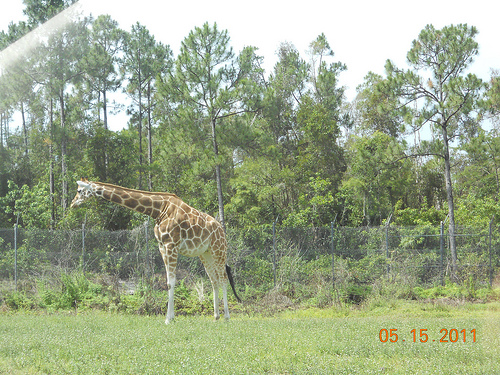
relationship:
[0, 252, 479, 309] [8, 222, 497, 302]
bush growing alongside fence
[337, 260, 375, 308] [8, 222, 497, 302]
bush growing alongside fence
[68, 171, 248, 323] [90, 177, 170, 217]
giraffe lowering neck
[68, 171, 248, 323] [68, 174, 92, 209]
giraffe bowing head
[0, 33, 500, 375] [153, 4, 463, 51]
area of sky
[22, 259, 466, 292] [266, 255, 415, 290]
row of shrubs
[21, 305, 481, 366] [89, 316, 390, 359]
field of grass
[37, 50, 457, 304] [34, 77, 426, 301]
exhibit at zoo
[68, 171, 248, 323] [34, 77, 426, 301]
giraffe at zoo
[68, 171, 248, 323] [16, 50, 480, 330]
giraffe at zoo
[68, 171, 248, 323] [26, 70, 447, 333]
giraffe in enclosure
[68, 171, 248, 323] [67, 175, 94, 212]
giraffe has head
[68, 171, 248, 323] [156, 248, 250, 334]
giraffe has legs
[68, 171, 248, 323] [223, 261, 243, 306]
giraffe has tail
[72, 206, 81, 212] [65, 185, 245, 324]
nose on giraffe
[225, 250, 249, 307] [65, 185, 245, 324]
tail on giraffe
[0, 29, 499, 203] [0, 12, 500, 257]
leaves in tree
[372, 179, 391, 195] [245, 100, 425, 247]
leaves in tree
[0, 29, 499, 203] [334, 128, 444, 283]
leaves in tree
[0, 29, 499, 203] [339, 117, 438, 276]
leaves in tree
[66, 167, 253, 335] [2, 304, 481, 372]
animal in field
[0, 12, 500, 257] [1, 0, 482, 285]
tree standing in woods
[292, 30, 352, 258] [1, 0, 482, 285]
tree standing in woods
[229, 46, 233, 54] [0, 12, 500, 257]
needle growing on tree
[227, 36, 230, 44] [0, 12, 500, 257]
needle growing on tree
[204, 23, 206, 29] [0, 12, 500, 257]
needle growing on tree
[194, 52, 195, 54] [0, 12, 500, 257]
needle growing on tree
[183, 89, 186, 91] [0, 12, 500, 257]
needle growing on tree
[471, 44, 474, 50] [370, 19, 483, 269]
needle growing on tree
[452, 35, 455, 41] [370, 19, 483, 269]
needle growing on tree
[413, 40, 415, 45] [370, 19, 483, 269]
needle growing on tree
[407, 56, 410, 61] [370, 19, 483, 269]
needle growing on tree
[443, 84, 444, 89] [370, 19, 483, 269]
needle growing on tree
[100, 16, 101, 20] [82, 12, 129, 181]
needle growing on tree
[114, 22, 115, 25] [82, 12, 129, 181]
needle growing on tree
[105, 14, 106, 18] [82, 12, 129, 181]
needle growing on tree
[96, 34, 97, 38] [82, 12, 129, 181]
needle growing on tree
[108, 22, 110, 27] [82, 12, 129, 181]
needle growing on tree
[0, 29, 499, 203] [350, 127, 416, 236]
leaves growing on tree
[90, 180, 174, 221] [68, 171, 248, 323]
neck belonging to giraffe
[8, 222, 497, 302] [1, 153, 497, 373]
fence in zoo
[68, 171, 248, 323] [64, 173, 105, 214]
giraffe has head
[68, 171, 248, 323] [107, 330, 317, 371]
giraffe standing grass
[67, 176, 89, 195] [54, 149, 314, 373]
eye of giraffe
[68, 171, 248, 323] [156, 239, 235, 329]
giraffe has legs